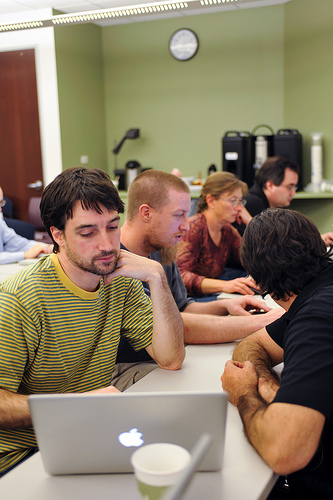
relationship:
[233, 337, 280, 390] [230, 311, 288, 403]
hair on arm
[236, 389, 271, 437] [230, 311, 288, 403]
hair on arm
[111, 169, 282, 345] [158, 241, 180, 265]
man with beard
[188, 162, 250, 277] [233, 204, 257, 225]
woman leaning on hand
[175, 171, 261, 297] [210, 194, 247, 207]
woman wearing glasses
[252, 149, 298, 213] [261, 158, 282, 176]
man with hair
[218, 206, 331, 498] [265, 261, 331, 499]
man wearing shirt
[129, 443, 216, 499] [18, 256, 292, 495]
cup on table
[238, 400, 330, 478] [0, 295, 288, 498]
arm on table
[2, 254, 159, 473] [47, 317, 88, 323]
shirt with stripes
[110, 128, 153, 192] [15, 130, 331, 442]
projector in classroom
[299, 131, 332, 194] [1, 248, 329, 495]
cups on table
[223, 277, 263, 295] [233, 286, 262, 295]
hand on mouse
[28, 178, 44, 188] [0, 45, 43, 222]
handle for door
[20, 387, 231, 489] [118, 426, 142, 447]
computer with label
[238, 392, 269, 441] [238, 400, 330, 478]
hair on arm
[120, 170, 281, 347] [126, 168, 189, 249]
man with head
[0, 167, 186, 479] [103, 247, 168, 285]
man leaning on hand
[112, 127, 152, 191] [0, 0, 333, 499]
projector at back of classroom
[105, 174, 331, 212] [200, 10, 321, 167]
counter along wall